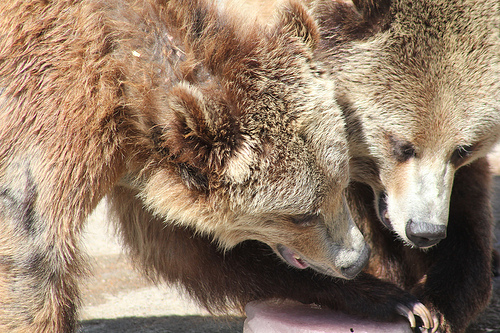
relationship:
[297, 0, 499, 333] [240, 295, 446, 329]
bear clawing object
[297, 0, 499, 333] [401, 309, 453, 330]
bear has claws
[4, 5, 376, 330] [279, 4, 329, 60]
bear has ear